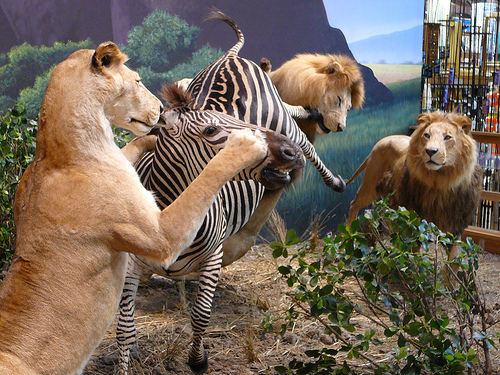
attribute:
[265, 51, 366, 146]
lion — brown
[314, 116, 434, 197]
lion — brown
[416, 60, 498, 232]
bookcase — tall 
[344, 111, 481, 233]
lion — stuffed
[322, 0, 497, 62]
sky — blue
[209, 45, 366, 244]
lion — female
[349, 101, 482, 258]
lion — brown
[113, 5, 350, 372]
zebra — black, white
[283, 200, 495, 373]
leaves — green